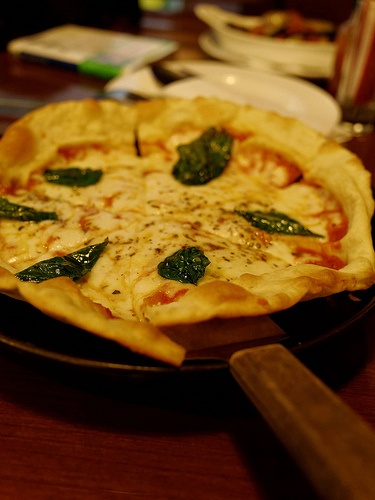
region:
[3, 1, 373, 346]
A thin-crust pizza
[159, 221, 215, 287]
A basil leaf topping a pizza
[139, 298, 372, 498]
A pizza server.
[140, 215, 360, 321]
A slice of pizza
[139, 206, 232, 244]
Cheese on a pizza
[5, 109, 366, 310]
A pizza with toppings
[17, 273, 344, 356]
Pizza crust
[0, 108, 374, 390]
A pizza on a tray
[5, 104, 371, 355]
A fresh pizza that nobody has eaten yet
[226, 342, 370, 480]
A wooden handle on the pizza server.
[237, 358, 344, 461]
Handle on pizza dish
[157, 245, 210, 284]
Spinach on the pizza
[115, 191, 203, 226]
Cheese on the pizza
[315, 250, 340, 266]
Tomato sauce of the pizza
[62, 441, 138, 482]
The table is brown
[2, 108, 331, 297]
A small cooked pizza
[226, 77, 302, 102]
White plate behind pizza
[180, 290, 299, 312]
Crust of cooked pizza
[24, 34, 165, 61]
White book behind pizza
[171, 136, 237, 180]
A large piece of spinach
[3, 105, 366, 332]
a pizza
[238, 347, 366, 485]
a wooden handle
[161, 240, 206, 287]
a cooked basil leaf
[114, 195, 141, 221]
melted cheese on a pizza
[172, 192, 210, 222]
dry herbs on a pizza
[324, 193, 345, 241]
tomato sauce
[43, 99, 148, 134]
a pizza crust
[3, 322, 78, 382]
a black metal pan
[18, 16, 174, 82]
a magazine on a table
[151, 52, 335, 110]
a white plate with a napkin and utensils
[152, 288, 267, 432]
Serving spatula on pan.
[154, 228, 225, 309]
Green leaf spice on pizza.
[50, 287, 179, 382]
Metal pan under pizza.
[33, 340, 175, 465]
Wood surface on table top.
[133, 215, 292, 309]
Melted cheese on pizza.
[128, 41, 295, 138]
Silver ware wrapped in napkin.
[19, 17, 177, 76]
Folded newspaper on table.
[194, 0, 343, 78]
White boat dish with food.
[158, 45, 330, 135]
White circular plate on table.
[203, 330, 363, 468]
Wooden handle on spatula.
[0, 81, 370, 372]
Pizza is on a plate.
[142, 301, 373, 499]
A spatula is under the pizza.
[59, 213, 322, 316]
The pizza has cheese on it.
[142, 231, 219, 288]
Spinach leaves are on the pizza.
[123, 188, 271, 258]
Seasoning is on the pizza.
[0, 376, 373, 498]
The plate is on a table.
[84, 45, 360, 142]
An empty plate is behind the pizza.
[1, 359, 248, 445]
The plate's shadow is on the table.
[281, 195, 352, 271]
The pizza contains tomato sauce.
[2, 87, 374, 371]
The pizza has been sliced.